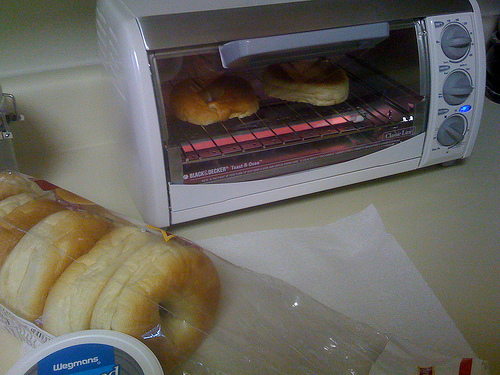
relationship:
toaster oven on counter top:
[90, 1, 493, 236] [3, 77, 497, 372]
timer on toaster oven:
[429, 98, 474, 158] [90, 1, 493, 236]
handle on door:
[207, 16, 405, 64] [141, 31, 449, 196]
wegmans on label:
[33, 343, 128, 371] [16, 339, 156, 374]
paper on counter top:
[139, 187, 495, 373] [3, 77, 497, 372]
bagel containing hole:
[162, 62, 265, 137] [196, 87, 224, 109]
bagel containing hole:
[257, 49, 354, 115] [289, 68, 318, 86]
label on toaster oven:
[168, 154, 383, 193] [90, 1, 493, 236]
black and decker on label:
[182, 161, 231, 184] [168, 154, 383, 193]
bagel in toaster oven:
[162, 62, 265, 137] [90, 1, 493, 236]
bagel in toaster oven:
[257, 49, 354, 115] [90, 1, 493, 236]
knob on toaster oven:
[433, 20, 479, 62] [90, 1, 493, 236]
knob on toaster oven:
[437, 68, 474, 106] [90, 1, 493, 236]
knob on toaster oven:
[429, 98, 474, 158] [90, 1, 493, 236]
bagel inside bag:
[92, 231, 239, 364] [0, 169, 403, 375]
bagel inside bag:
[37, 218, 168, 345] [0, 169, 403, 375]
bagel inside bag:
[0, 205, 117, 322] [0, 169, 403, 375]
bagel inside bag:
[0, 181, 69, 250] [0, 169, 403, 375]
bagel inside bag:
[0, 166, 35, 196] [0, 169, 403, 375]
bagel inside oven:
[162, 62, 265, 137] [90, 1, 493, 236]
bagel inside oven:
[257, 49, 354, 115] [90, 1, 493, 236]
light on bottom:
[169, 108, 406, 167] [169, 192, 442, 215]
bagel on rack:
[162, 62, 265, 137] [159, 40, 431, 178]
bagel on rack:
[257, 49, 354, 115] [159, 40, 431, 178]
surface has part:
[3, 77, 497, 372] [403, 189, 500, 292]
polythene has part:
[139, 187, 495, 373] [299, 232, 387, 291]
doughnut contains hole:
[162, 62, 265, 137] [196, 87, 224, 109]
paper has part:
[139, 187, 495, 373] [299, 232, 387, 291]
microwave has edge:
[90, 1, 493, 236] [88, 1, 146, 209]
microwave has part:
[90, 1, 493, 236] [415, 13, 492, 179]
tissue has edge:
[139, 187, 495, 373] [366, 199, 494, 361]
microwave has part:
[90, 1, 493, 236] [207, 16, 405, 64]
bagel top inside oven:
[162, 62, 265, 137] [90, 1, 493, 236]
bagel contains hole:
[162, 62, 265, 137] [196, 87, 224, 109]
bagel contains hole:
[257, 49, 354, 115] [289, 68, 318, 86]